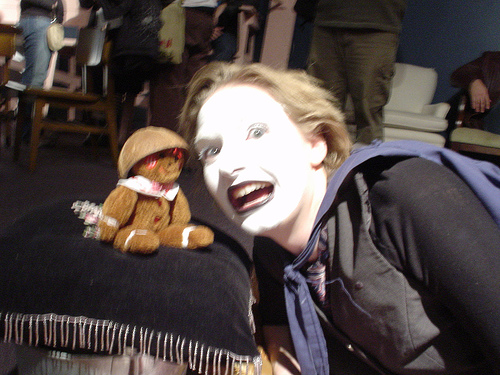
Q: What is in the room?
A: A chair.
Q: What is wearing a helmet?
A: A teddy bear.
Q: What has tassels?
A: Black pillow.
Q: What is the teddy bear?
A: Brown.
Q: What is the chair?
A: White.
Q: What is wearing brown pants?
A: The man.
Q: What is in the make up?
A: The scary mime.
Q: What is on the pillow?
A: The brown teddy bear.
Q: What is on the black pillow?
A: Tassels.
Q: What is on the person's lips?
A: Black lipstick.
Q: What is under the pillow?
A: A stool.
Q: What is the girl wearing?
A: A cape.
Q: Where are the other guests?
A: Behind the girl.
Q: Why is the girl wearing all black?
A: For the party.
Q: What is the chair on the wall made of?
A: White leather.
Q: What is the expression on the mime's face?
A: Surprise.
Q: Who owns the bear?
A: A shopkeeper.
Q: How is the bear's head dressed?
A: In a hat.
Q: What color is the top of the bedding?
A: Blue.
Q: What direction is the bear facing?
A: Right.